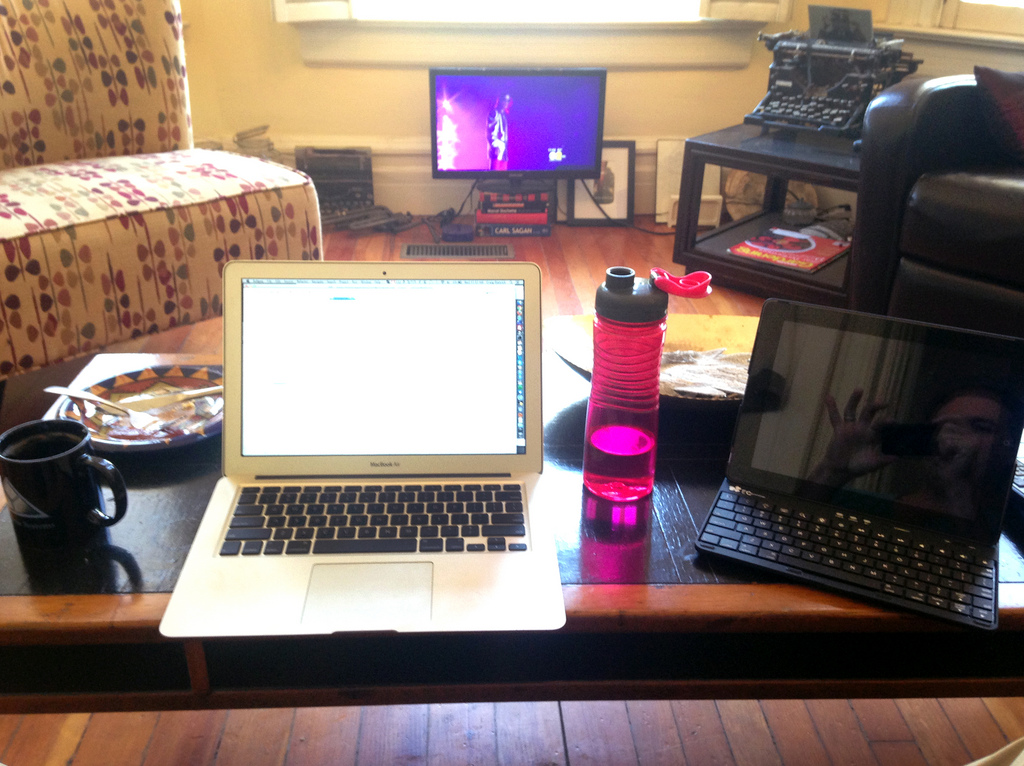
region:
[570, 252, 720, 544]
bottle on coffee table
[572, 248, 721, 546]
bottle on table is pink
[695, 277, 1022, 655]
right laptop is black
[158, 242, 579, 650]
left laptop is white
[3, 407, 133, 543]
coffee mug next to laptop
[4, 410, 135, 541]
coffee mug is black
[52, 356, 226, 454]
paper plate on table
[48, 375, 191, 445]
fork on paper plate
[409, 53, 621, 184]
television behind books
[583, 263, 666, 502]
a hot pink water bottle with a black top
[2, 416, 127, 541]
a black coffe mug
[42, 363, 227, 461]
dirty dinner plate with silverware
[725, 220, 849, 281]
magazine on the bottom shelf of a table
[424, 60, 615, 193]
flat screen tv sitting on a pile of books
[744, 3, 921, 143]
old fashioned black type writer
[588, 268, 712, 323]
black cap of a pink water bottle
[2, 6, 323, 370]
off white couch with multi colored dots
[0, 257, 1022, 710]
white laptop on coffee table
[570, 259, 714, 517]
lid open on pink water bottle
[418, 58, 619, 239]
flat screen TV on a stack of books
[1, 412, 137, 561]
white logo on black coffee mug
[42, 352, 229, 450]
fork on blue and orange plate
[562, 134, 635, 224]
cat picture in black frame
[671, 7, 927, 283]
typewriter on end table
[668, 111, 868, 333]
magazine under end table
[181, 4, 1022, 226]
window in off-white wall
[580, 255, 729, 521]
red water bottle with black top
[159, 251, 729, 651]
red water bottle with black top beside white laptop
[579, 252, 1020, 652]
red water bottle with black top beside black laptop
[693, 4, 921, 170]
old style type writer on table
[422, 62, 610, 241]
tv sitting on stack of books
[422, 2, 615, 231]
tv sitting on stack of books by window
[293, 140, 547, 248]
toolbox in floor by tv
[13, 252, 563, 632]
coffee mug beside of laptop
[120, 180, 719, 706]
this is a laptop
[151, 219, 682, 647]
the laptop is on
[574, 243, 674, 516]
water bottle on the table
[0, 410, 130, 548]
coffee mug on the table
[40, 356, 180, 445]
silver fork on the plate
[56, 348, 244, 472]
blue and yellow plate on the table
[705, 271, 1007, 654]
black laptop on the table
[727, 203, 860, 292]
book under the table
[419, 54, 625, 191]
TV on the floor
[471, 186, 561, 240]
stack of books on the floor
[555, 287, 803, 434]
brown bowl on the table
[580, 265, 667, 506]
a translucent pink water bottle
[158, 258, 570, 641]
a silver laptop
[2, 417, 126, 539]
a black coffee mug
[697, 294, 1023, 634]
a black laptop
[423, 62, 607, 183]
an illuminated TV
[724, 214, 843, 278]
a magazine under the table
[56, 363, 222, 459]
a round plate with a fork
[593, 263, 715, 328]
black lid on a water bottle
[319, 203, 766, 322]
a hardwood floor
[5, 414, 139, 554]
black mug on the table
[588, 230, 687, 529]
water bottle is pink and black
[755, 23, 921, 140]
typewriter on the table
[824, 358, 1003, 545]
man reflection in the screen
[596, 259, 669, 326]
black top on the water bottle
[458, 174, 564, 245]
book stacked under the tv